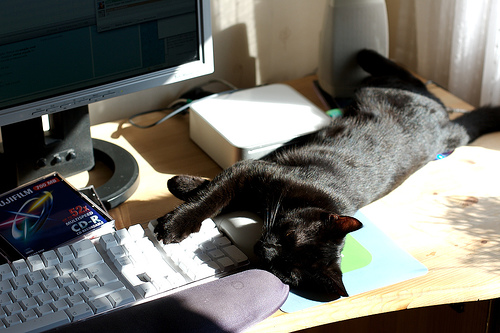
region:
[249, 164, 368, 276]
One cat is on the table.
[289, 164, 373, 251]
Cat is black color.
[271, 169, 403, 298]
Cat is lying on the table.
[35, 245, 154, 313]
Key board is white color.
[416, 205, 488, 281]
table is brown color.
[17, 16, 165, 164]
Monitor screen is off.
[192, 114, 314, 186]
Router is white color.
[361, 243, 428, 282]
Mouse pad is green color.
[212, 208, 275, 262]
One mouse is on the table.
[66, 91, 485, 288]
Sunlight reflection is seen on the table.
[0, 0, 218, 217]
a computer monitor on a desk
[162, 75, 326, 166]
a white router on a desk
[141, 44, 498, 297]
a black cat laying on a desk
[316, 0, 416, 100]
cat's foot resting on a computer speaker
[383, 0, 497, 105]
a white curtain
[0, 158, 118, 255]
CD-R cases resting on a computer monitor's base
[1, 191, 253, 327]
cat resting its paws on a white keyboard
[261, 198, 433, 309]
cat's head resting on a mouse pad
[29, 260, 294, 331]
wrist pad next to keyboard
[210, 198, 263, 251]
white computer mouse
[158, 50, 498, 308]
black cat on the brown desk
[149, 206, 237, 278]
black cat paw on keyboard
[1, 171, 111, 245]
Blue CD-R Case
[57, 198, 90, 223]
red print on the blue case reading 52x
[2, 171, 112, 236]
blue fujifilm case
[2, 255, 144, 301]
many keys on the keyboard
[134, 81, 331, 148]
white modem on the desk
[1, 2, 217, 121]
computer monitor screen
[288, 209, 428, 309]
mouse pad under the cat's head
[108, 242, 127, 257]
white key on the keyboard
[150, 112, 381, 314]
The cat is sleeping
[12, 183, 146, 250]
There are cdrs in front of the keyboard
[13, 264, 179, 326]
The keyboard is white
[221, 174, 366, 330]
The cat is dark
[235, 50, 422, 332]
The cat is laying in the sun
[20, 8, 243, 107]
The computer is on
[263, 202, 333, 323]
The cat's eyes are closed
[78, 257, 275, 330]
There is a wrist support on the desk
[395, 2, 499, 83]
There is a curtain behind the cat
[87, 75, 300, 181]
There are computer cords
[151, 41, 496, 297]
Black cat lying down on a desk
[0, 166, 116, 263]
Plastic CD cases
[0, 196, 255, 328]
White computer keyboard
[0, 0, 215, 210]
Black and silver computer monitor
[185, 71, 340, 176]
White Apple Mac Mini computer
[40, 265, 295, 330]
Gel wristpad for keyboards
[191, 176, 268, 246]
Computer mouse next to cat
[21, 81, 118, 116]
Buttons on front of computer monitor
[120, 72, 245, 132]
Cables connected to a computer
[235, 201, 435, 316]
Blue and green mouse pad